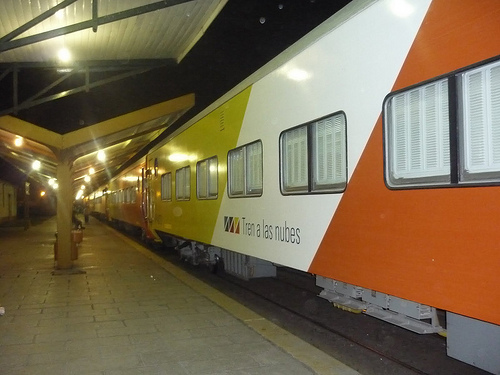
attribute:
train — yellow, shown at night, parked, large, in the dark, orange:
[82, 1, 499, 374]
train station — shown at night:
[1, 0, 500, 374]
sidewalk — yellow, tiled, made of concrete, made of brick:
[1, 210, 358, 374]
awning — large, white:
[1, 1, 231, 199]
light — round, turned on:
[52, 47, 75, 67]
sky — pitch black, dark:
[3, 1, 352, 194]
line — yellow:
[91, 210, 363, 374]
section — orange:
[309, 1, 497, 319]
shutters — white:
[392, 78, 451, 182]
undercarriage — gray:
[173, 236, 500, 375]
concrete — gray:
[126, 230, 499, 374]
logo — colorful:
[221, 214, 303, 248]